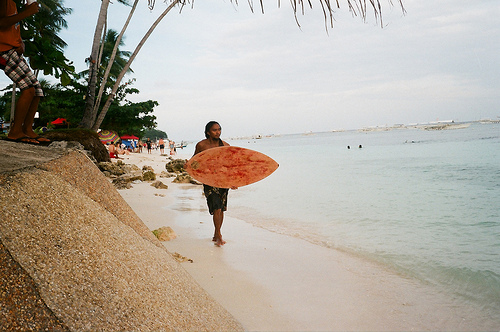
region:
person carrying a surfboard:
[171, 111, 288, 251]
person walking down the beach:
[178, 116, 257, 248]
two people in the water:
[338, 137, 369, 155]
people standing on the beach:
[132, 131, 183, 161]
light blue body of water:
[205, 125, 497, 307]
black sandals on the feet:
[11, 128, 53, 146]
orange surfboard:
[180, 148, 277, 190]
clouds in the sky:
[18, 1, 497, 130]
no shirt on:
[183, 136, 233, 172]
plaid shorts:
[2, 51, 39, 90]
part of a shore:
[279, 279, 305, 313]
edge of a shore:
[331, 235, 374, 294]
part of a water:
[378, 183, 428, 244]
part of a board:
[225, 105, 258, 154]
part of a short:
[198, 188, 225, 214]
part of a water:
[400, 145, 445, 212]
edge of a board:
[231, 154, 265, 191]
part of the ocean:
[312, 254, 369, 281]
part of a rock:
[28, 220, 34, 250]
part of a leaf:
[144, 105, 151, 114]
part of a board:
[245, 164, 273, 204]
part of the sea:
[403, 215, 414, 230]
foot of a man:
[38, 126, 55, 148]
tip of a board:
[266, 159, 285, 179]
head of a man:
[336, 127, 358, 176]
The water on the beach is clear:
[341, 151, 486, 261]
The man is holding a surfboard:
[183, 144, 287, 189]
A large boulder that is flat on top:
[3, 140, 198, 330]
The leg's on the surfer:
[203, 203, 239, 246]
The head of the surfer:
[203, 119, 227, 141]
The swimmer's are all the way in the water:
[333, 138, 375, 155]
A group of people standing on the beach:
[111, 130, 179, 160]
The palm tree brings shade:
[73, 0, 419, 133]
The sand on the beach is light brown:
[199, 250, 474, 329]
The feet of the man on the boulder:
[1, 117, 55, 148]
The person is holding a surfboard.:
[174, 112, 251, 247]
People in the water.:
[322, 123, 390, 174]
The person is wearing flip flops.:
[1, 115, 55, 158]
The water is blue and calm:
[318, 148, 491, 247]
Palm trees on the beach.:
[61, 8, 141, 135]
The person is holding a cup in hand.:
[16, 5, 51, 30]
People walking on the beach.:
[109, 115, 175, 154]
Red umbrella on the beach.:
[116, 123, 138, 140]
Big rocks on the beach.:
[72, 142, 190, 192]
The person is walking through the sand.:
[173, 100, 272, 247]